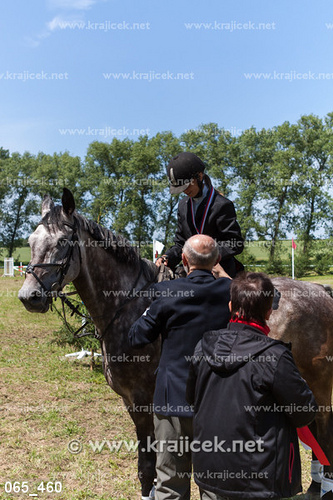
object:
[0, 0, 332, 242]
sky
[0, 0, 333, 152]
cloud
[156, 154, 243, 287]
jockey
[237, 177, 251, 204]
leaves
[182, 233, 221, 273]
head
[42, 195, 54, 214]
ear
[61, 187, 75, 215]
ear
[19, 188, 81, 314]
head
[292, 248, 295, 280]
pole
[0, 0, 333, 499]
water mark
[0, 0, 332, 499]
photo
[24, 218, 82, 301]
bridle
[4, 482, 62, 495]
number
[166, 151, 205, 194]
hat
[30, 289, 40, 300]
nostrils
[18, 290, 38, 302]
nose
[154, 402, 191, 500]
pants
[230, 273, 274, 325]
hair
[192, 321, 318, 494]
jacket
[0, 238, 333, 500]
grass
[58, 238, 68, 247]
eye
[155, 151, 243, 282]
man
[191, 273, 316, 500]
man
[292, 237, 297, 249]
flag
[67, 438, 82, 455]
copyright symbol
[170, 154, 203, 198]
head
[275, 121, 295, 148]
leaves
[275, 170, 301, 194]
leaves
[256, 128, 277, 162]
leaves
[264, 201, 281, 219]
leaves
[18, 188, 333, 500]
horse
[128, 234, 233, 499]
balding man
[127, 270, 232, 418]
black jacket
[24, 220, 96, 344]
harnass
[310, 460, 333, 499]
wraps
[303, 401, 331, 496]
leg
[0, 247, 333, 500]
field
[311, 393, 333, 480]
leg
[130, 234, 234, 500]
man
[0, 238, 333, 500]
ground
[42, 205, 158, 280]
mane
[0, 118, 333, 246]
tree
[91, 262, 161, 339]
reins